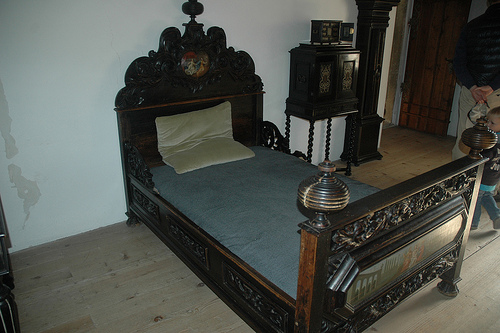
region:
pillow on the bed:
[152, 108, 252, 165]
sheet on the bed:
[235, 195, 277, 222]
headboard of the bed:
[150, 51, 270, 104]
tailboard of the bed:
[341, 187, 457, 238]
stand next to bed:
[279, 46, 346, 120]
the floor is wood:
[91, 245, 173, 291]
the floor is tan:
[92, 245, 153, 280]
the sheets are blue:
[218, 186, 283, 220]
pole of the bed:
[305, 175, 340, 222]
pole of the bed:
[180, 8, 209, 46]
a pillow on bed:
[155, 97, 260, 174]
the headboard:
[114, 7, 266, 142]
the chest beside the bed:
[284, 14, 360, 171]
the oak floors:
[12, 127, 499, 332]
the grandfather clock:
[342, 0, 394, 167]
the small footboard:
[296, 118, 488, 331]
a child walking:
[468, 107, 498, 230]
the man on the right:
[449, 0, 499, 207]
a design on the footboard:
[326, 169, 480, 332]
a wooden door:
[394, 0, 471, 132]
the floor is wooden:
[12, 231, 207, 331]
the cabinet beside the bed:
[264, 21, 376, 128]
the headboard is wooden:
[114, 3, 267, 148]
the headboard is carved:
[101, 2, 282, 151]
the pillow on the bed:
[149, 104, 266, 171]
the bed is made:
[140, 154, 385, 259]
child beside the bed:
[462, 98, 498, 220]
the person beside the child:
[442, 0, 496, 170]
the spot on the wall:
[2, 151, 53, 235]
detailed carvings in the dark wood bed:
[90, 2, 470, 331]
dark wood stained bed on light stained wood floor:
[54, 247, 217, 326]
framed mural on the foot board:
[315, 205, 477, 320]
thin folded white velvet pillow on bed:
[147, 97, 258, 187]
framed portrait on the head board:
[176, 45, 221, 87]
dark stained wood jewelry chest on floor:
[281, 18, 367, 200]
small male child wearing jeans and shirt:
[463, 88, 497, 240]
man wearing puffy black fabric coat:
[451, 21, 498, 106]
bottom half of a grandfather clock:
[338, 0, 398, 171]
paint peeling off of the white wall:
[2, 156, 49, 242]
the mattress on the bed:
[147, 143, 382, 298]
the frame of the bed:
[113, 0, 495, 331]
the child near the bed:
[471, 106, 498, 228]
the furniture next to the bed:
[284, 20, 364, 177]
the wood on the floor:
[7, 124, 497, 331]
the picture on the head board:
[177, 48, 212, 78]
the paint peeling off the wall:
[0, 81, 40, 229]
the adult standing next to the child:
[452, 0, 498, 161]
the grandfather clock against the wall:
[340, 0, 395, 167]